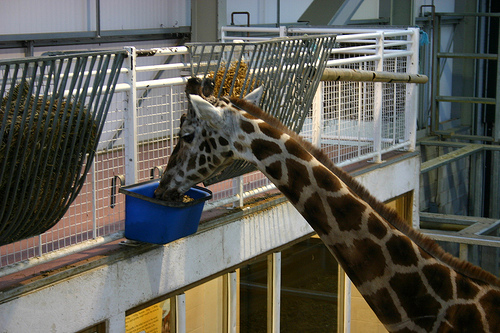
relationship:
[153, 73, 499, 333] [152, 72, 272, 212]
giraffe has head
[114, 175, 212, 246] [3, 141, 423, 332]
container on ledge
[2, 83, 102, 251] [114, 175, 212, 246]
hay in container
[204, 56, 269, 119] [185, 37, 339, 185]
hay in container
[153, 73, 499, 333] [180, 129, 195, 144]
giraffe has eye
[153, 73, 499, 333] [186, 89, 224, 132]
giraffe has ear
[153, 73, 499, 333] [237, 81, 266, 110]
giraffe has ear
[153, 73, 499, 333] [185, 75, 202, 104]
giraffe has horn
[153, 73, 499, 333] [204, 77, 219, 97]
giraffe has horn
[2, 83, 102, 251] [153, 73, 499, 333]
hay intended for giraffe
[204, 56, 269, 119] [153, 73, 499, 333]
hay intended for giraffe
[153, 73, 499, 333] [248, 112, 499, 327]
giraffe has neck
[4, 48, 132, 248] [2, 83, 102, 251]
container holds hay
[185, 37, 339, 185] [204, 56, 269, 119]
container holds hay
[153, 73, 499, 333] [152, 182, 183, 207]
giraffe has mouth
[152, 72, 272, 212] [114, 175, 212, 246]
head in container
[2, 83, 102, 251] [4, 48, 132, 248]
hay in container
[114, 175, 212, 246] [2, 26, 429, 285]
container attached to fence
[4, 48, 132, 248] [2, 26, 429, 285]
container attached to fence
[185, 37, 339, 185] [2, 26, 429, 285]
container attached to fence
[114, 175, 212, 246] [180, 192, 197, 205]
container holding food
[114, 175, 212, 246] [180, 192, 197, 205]
container holds food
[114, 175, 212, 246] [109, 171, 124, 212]
container has hook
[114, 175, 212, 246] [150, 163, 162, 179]
container has hook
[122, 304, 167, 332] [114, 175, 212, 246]
sign underneath container